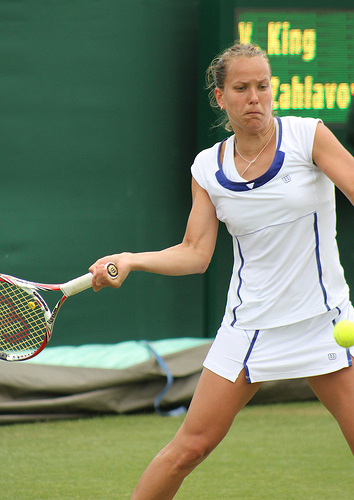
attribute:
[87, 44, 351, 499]
player — female, caucassian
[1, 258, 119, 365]
racket — red, white, detailed, swung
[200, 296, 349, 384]
skirt — blue, white, trimmed blue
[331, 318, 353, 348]
ball — yellow, in air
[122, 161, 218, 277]
arm — out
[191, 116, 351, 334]
top — blue, white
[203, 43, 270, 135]
hair — blonde, pulled back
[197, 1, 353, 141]
sign — worded, green, yellow, scoreboard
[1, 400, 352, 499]
grass — green, tennis court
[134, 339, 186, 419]
strap — blue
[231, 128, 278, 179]
necklace — silver, white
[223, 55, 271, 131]
face — concentrating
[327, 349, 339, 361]
logo — w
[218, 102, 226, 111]
earring — small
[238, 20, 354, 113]
words — yellow